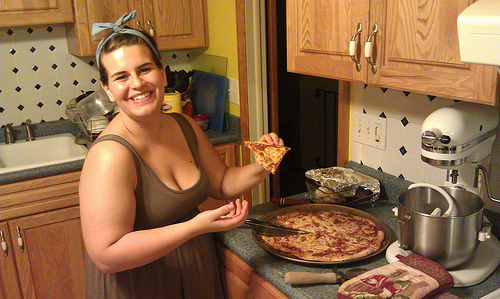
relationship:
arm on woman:
[77, 144, 193, 281] [76, 28, 283, 297]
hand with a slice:
[196, 197, 249, 237] [245, 137, 292, 176]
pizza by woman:
[259, 208, 382, 265] [76, 28, 283, 297]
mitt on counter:
[338, 251, 455, 298] [213, 185, 500, 298]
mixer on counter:
[386, 107, 497, 288] [213, 185, 500, 298]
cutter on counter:
[278, 264, 372, 288] [213, 185, 500, 298]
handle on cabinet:
[362, 24, 380, 75] [363, 0, 498, 109]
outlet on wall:
[351, 111, 385, 145] [349, 82, 498, 211]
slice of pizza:
[245, 137, 292, 176] [259, 208, 382, 265]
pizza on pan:
[259, 208, 382, 265] [249, 203, 391, 266]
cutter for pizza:
[278, 264, 372, 288] [259, 208, 382, 265]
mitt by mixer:
[338, 251, 455, 298] [386, 107, 497, 288]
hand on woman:
[196, 197, 249, 237] [76, 28, 283, 297]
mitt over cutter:
[338, 251, 455, 298] [278, 264, 372, 288]